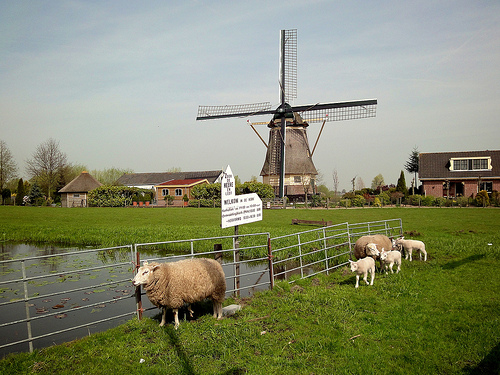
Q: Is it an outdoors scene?
A: Yes, it is outdoors.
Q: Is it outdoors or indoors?
A: It is outdoors.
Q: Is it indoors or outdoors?
A: It is outdoors.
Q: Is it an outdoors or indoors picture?
A: It is outdoors.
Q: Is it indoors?
A: No, it is outdoors.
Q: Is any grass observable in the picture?
A: Yes, there is grass.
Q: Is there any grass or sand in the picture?
A: Yes, there is grass.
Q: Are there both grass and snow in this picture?
A: No, there is grass but no snow.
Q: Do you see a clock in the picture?
A: No, there are no clocks.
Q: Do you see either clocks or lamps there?
A: No, there are no clocks or lamps.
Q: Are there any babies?
A: Yes, there is a baby.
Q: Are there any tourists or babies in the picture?
A: Yes, there is a baby.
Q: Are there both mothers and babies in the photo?
A: No, there is a baby but no mothers.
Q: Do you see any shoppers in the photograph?
A: No, there are no shoppers.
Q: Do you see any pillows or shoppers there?
A: No, there are no shoppers or pillows.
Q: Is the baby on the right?
A: Yes, the baby is on the right of the image.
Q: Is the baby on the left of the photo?
A: No, the baby is on the right of the image.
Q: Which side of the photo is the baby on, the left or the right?
A: The baby is on the right of the image.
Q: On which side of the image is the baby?
A: The baby is on the right of the image.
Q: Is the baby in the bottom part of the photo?
A: Yes, the baby is in the bottom of the image.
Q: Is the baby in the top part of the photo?
A: No, the baby is in the bottom of the image.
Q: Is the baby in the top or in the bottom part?
A: The baby is in the bottom of the image.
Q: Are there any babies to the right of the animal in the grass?
A: Yes, there is a baby to the right of the animal.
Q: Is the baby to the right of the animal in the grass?
A: Yes, the baby is to the right of the animal.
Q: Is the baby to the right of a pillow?
A: No, the baby is to the right of the animal.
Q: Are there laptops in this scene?
A: Yes, there is a laptop.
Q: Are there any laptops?
A: Yes, there is a laptop.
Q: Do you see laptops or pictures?
A: Yes, there is a laptop.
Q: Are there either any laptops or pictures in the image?
A: Yes, there is a laptop.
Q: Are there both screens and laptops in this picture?
A: No, there is a laptop but no screens.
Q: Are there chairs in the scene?
A: No, there are no chairs.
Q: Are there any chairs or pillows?
A: No, there are no chairs or pillows.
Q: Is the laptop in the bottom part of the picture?
A: Yes, the laptop is in the bottom of the image.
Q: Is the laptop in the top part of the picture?
A: No, the laptop is in the bottom of the image.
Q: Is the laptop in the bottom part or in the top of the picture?
A: The laptop is in the bottom of the image.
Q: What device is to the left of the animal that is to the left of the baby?
A: The device is a laptop.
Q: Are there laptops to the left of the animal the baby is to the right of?
A: Yes, there is a laptop to the left of the animal.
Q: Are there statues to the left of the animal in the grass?
A: No, there is a laptop to the left of the animal.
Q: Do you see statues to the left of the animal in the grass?
A: No, there is a laptop to the left of the animal.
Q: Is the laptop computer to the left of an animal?
A: Yes, the laptop computer is to the left of an animal.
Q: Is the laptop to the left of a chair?
A: No, the laptop is to the left of an animal.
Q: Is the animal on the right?
A: Yes, the animal is on the right of the image.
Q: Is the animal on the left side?
A: No, the animal is on the right of the image.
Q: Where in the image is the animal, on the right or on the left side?
A: The animal is on the right of the image.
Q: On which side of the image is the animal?
A: The animal is on the right of the image.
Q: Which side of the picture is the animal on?
A: The animal is on the right of the image.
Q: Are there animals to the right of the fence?
A: Yes, there is an animal to the right of the fence.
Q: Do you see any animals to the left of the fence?
A: No, the animal is to the right of the fence.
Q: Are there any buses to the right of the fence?
A: No, there is an animal to the right of the fence.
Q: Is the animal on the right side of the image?
A: Yes, the animal is on the right of the image.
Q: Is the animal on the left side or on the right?
A: The animal is on the right of the image.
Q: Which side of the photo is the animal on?
A: The animal is on the right of the image.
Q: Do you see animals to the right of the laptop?
A: Yes, there is an animal to the right of the laptop.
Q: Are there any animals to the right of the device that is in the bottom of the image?
A: Yes, there is an animal to the right of the laptop.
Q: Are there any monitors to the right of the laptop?
A: No, there is an animal to the right of the laptop.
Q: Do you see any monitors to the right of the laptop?
A: No, there is an animal to the right of the laptop.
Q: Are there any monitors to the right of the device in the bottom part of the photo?
A: No, there is an animal to the right of the laptop.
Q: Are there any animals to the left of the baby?
A: Yes, there is an animal to the left of the baby.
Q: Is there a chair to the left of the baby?
A: No, there is an animal to the left of the baby.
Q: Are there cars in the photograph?
A: No, there are no cars.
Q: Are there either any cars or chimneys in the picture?
A: No, there are no cars or chimneys.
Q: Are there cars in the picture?
A: No, there are no cars.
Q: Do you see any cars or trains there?
A: No, there are no cars or trains.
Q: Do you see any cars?
A: No, there are no cars.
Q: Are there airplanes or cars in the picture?
A: No, there are no cars or airplanes.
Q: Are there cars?
A: No, there are no cars.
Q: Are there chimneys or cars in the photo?
A: No, there are no cars or chimneys.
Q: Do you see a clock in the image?
A: No, there are no clocks.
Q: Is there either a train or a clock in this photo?
A: No, there are no clocks or trains.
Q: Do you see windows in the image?
A: Yes, there is a window.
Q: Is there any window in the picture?
A: Yes, there is a window.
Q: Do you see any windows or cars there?
A: Yes, there is a window.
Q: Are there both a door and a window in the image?
A: No, there is a window but no doors.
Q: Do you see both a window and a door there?
A: No, there is a window but no doors.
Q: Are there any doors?
A: No, there are no doors.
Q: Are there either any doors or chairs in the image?
A: No, there are no doors or chairs.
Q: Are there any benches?
A: No, there are no benches.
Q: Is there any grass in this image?
A: Yes, there is grass.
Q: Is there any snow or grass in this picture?
A: Yes, there is grass.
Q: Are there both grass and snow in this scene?
A: No, there is grass but no snow.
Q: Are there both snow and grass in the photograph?
A: No, there is grass but no snow.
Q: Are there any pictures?
A: No, there are no pictures.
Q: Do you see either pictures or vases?
A: No, there are no pictures or vases.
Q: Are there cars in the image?
A: No, there are no cars.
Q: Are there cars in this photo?
A: No, there are no cars.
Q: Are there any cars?
A: No, there are no cars.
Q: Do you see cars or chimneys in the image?
A: No, there are no cars or chimneys.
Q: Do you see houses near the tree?
A: Yes, there is a house near the tree.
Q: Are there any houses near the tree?
A: Yes, there is a house near the tree.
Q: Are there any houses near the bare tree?
A: Yes, there is a house near the tree.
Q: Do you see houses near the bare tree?
A: Yes, there is a house near the tree.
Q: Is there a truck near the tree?
A: No, there is a house near the tree.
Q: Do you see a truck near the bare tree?
A: No, there is a house near the tree.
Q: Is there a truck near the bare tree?
A: No, there is a house near the tree.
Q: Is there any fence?
A: Yes, there is a fence.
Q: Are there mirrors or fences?
A: Yes, there is a fence.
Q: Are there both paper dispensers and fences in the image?
A: No, there is a fence but no paper dispensers.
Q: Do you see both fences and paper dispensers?
A: No, there is a fence but no paper dispensers.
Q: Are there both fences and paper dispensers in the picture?
A: No, there is a fence but no paper dispensers.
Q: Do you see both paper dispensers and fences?
A: No, there is a fence but no paper dispensers.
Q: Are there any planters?
A: No, there are no planters.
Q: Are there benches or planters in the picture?
A: No, there are no planters or benches.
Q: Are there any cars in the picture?
A: No, there are no cars.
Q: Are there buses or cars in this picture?
A: No, there are no cars or buses.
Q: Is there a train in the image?
A: No, there are no trains.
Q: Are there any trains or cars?
A: No, there are no trains or cars.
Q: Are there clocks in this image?
A: No, there are no clocks.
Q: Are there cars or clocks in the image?
A: No, there are no clocks or cars.